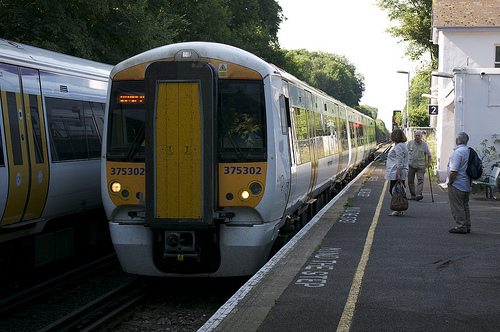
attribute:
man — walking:
[404, 127, 442, 208]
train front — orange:
[102, 38, 278, 283]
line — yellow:
[324, 173, 398, 331]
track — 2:
[424, 102, 442, 120]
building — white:
[471, 100, 484, 127]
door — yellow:
[142, 72, 213, 272]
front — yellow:
[78, 50, 259, 211]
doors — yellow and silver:
[2, 95, 53, 214]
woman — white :
[387, 125, 411, 218]